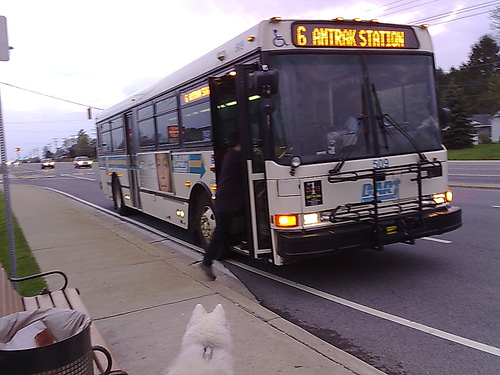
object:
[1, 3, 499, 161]
sky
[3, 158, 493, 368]
street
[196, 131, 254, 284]
person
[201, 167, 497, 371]
ground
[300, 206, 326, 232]
light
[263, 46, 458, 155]
window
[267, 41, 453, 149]
windshield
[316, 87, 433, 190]
driver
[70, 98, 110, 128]
light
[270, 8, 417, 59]
words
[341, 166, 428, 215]
logo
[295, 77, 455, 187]
wipers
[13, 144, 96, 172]
cars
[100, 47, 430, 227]
person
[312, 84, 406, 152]
man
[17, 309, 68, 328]
bag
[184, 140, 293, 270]
man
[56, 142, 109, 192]
head lights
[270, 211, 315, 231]
headlights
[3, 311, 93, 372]
garbage can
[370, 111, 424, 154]
windshield wipers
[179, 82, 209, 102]
light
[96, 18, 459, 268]
bus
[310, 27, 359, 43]
light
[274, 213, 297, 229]
light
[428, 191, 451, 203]
light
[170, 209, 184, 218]
light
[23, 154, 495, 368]
road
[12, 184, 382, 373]
sidewalk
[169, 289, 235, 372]
dog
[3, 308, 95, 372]
trash can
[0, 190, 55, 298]
grass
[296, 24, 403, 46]
letters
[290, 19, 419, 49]
sign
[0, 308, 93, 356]
top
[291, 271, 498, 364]
line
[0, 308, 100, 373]
can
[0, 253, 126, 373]
bench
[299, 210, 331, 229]
head light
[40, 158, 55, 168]
car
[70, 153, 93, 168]
car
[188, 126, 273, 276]
passenger